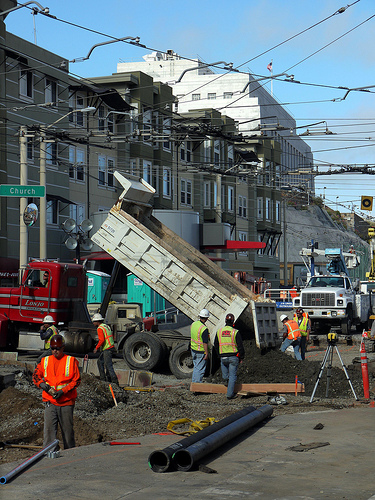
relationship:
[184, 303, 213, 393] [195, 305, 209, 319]
worker wears vest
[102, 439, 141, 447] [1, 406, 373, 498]
tool laying on ground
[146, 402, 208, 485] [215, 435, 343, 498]
sewer pipe sitting on ground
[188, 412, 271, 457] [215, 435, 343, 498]
sewer pipe sitting on ground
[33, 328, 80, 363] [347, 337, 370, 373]
man wearing a safety cone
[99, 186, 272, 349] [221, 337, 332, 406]
dump truck dumping dirt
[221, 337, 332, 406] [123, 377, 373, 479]
dirt on ground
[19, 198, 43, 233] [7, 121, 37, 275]
mirror attached to pole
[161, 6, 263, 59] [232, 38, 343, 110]
sky filled with wires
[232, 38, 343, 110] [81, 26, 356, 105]
wires and cables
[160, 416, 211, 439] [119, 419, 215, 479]
strap laying on ground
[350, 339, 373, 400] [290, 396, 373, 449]
pole standing in ground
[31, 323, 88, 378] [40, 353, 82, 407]
man wearing safety clothes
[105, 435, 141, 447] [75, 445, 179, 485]
tool laying on ground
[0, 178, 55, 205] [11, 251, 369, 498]
sign with name of street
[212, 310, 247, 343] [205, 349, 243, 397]
person wearing jeans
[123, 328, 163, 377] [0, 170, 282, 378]
tire on dump truck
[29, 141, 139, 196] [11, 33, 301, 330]
windows on building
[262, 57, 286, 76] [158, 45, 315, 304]
flag on top of building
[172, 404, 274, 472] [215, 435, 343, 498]
sewer pipe on ground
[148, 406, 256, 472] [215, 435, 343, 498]
sewer pipe on ground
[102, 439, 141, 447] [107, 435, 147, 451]
tool with a handle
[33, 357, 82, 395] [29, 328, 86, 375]
vest on man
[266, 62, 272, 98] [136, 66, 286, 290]
flag on building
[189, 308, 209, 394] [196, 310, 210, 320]
worker wearing a helmet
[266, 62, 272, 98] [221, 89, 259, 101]
flag on roof